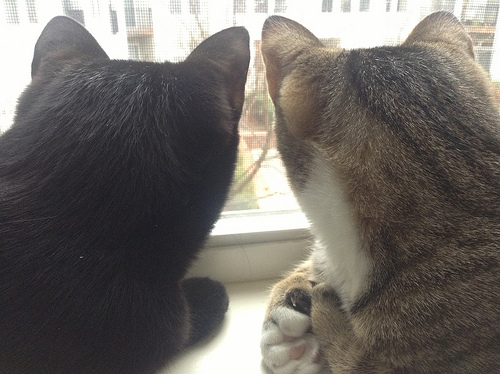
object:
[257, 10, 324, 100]
ear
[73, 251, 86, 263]
object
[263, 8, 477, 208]
chair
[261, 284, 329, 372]
big paw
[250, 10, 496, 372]
brown cat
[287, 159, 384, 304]
white throat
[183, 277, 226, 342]
paw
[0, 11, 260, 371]
cat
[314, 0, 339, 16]
windows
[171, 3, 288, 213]
tree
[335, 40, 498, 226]
stripes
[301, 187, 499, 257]
neck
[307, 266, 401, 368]
claw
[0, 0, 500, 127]
building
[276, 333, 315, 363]
pad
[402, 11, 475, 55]
ear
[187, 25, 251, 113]
ear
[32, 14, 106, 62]
ear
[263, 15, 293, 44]
hair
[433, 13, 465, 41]
hair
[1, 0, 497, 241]
window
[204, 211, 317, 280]
ledge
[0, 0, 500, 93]
back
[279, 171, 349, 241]
chin